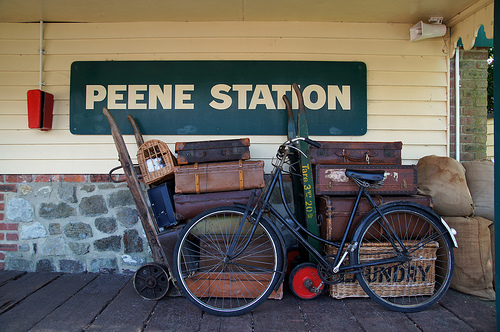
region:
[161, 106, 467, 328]
the bike is black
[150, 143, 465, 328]
the bike is black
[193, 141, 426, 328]
the bike is black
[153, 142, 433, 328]
the bike is black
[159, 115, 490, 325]
the bike is black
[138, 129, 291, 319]
a pile of suitcase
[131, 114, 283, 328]
a pile of suitcase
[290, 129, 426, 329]
a pile of suitcase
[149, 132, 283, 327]
a pile of suitcase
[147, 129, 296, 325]
a pile of suitcase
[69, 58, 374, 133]
a large black train station sign.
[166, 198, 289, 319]
a front bike tire.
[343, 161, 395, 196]
a bike seat tire on a bike.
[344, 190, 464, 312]
a rear bike tire on a bike.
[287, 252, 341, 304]
a pedal on a bike.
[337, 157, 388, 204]
a bike seat on a bike.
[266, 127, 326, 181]
a set of handle bars on a bike.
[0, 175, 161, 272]
A stone wall on a building.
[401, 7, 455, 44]
a loud speaker on a building.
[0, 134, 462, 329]
Blue bike on porch of station.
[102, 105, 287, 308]
Suitcases on wooden carrier.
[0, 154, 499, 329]
Large filled sacks on porch.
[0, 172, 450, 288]
Luggage and carriers leaning against brick wall.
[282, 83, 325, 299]
Red wheel on luggage carrier.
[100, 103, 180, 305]
Black wheel on luggage carrier.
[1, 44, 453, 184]
Large green sign that says PEENE STATION on building.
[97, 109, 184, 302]
Brown wicker basket on luggage carrier.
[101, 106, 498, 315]
the objects piled against the wall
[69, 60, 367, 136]
the sign on the wall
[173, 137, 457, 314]
the bike in front of the pile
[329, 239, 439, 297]
the trunk basket behind the bike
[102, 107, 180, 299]
the dolly near the pile of objects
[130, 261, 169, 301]
the wheel on the dolly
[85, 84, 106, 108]
the "P" on the sign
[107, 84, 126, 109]
the letter "E" on the sign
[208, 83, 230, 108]
the letter "S" on the sign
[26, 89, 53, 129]
the red object on the wall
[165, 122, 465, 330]
shiny black bicycle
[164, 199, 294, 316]
black rubber bicycle tire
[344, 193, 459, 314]
black rubber bicycle tire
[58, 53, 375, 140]
green and white station sign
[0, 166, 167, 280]
grey stone and red brick wall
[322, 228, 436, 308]
light brown wicker laundry basket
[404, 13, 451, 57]
white plastic loud speaker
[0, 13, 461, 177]
pale yellow vinyl siding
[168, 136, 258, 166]
dark brown leather suitcase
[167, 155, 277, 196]
light brown leather suitcase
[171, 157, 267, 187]
leather luggage waiting on the platform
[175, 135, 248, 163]
leather luggage waiting on the platform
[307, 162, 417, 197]
leather luggage waiting on the platform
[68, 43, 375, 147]
green and white sign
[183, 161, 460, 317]
bike lying against luggage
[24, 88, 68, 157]
red alarm on wall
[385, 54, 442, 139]
white siding on building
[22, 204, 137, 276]
wall is grey stone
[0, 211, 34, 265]
red brick on wall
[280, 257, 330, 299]
red and black wheel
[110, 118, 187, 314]
brown cart with luggage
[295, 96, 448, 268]
luggage is dark brown